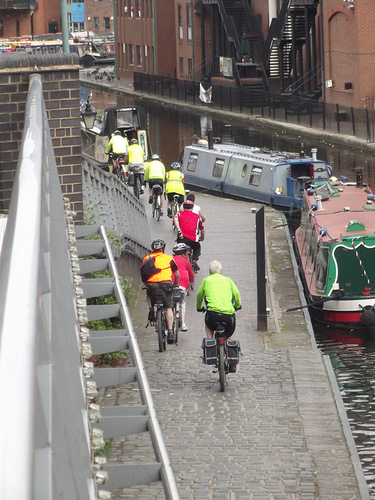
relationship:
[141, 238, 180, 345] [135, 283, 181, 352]
bike rider on a bike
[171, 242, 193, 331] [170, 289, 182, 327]
person on a bike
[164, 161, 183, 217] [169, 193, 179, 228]
person on a bike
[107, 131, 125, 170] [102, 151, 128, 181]
person on a bike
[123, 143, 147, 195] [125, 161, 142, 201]
man on a bike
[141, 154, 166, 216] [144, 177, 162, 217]
man on a bike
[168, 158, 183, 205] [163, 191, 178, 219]
person on a bike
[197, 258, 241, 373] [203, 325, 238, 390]
bike rider on a bike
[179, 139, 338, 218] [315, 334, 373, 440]
blue boat in water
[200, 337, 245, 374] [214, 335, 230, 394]
bags on side of a bike tire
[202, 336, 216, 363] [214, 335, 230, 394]
bag on side of a bike tire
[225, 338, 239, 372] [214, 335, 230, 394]
bag on side of a bike tire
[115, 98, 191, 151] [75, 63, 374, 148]
water between sidewalk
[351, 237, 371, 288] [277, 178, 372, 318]
decoration on boat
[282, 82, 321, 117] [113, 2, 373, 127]
stairs on building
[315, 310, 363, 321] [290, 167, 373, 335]
stripe on bottom of boat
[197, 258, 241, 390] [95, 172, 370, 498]
bike rider riding on sidewalk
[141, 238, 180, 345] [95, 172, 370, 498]
bike rider riding on sidewalk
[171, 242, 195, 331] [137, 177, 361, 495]
person riding on street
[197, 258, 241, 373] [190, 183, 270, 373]
bike rider riding on street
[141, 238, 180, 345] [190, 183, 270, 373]
bike rider riding on street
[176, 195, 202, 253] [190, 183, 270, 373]
rider riding on street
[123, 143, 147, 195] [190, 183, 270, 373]
man riding on street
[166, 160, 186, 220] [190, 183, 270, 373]
person riding on street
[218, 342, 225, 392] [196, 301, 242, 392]
bike tire on bike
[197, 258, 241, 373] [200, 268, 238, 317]
bike rider wearing a jacket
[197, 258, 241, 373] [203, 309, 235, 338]
bike rider wearing a shorts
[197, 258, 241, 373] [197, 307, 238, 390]
bike rider on top of a bike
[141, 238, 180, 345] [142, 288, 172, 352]
bike rider on top of a bike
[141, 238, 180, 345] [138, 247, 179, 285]
bike rider wearing a orange shirt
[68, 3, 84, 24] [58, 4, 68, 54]
sign attached to a pole